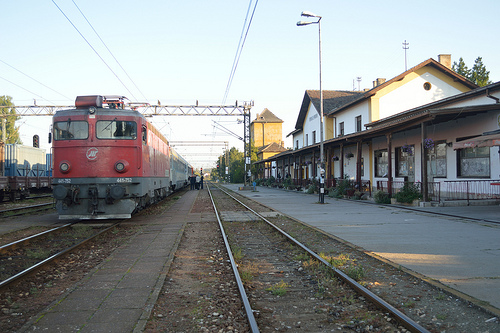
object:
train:
[48, 94, 193, 222]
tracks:
[0, 219, 123, 286]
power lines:
[52, 0, 151, 103]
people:
[188, 174, 196, 190]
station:
[247, 53, 499, 203]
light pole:
[297, 10, 325, 202]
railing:
[444, 180, 499, 204]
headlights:
[57, 161, 71, 173]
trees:
[451, 55, 492, 87]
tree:
[1, 92, 26, 144]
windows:
[52, 119, 138, 141]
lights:
[296, 11, 320, 26]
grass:
[267, 279, 290, 296]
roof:
[325, 53, 481, 114]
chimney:
[436, 53, 451, 67]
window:
[393, 142, 417, 178]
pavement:
[220, 181, 500, 312]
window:
[422, 81, 433, 91]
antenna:
[101, 97, 125, 109]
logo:
[85, 145, 100, 161]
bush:
[394, 182, 421, 203]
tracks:
[205, 178, 435, 331]